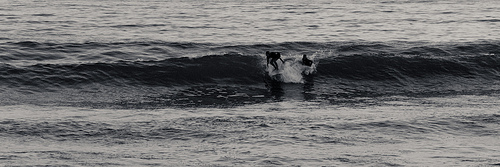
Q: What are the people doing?
A: Surfing.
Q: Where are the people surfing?
A: Water.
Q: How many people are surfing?
A: Two.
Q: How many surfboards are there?
A: Two.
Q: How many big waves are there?
A: One.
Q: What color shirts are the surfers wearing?
A: Black.